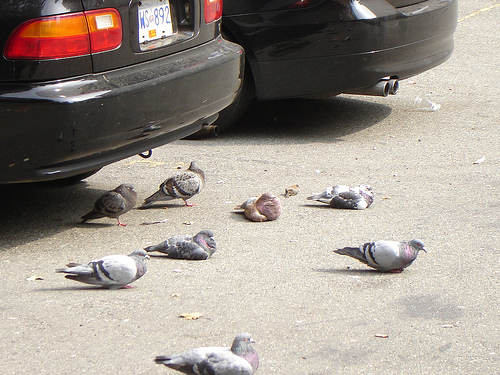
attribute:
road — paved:
[2, 1, 500, 373]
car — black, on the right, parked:
[179, 0, 460, 140]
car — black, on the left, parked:
[1, 1, 245, 188]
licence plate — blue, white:
[136, 0, 174, 46]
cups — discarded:
[410, 93, 443, 113]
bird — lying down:
[232, 186, 285, 224]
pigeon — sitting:
[331, 235, 431, 280]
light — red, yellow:
[1, 7, 125, 62]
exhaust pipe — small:
[192, 123, 221, 135]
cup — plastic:
[412, 94, 442, 114]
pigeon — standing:
[135, 158, 209, 212]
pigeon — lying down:
[141, 227, 220, 265]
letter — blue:
[143, 7, 152, 28]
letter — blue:
[138, 10, 146, 33]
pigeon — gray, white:
[152, 331, 262, 375]